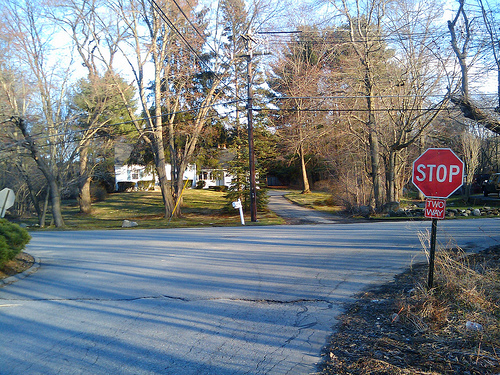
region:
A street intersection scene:
[4, 7, 496, 372]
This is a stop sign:
[411, 145, 466, 294]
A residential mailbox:
[231, 195, 247, 229]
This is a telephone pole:
[234, 19, 272, 223]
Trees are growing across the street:
[1, 0, 498, 225]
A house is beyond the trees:
[108, 134, 263, 194]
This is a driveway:
[260, 186, 350, 228]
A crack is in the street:
[1, 284, 343, 319]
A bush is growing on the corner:
[0, 217, 40, 285]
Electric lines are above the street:
[1, 2, 497, 149]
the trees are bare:
[269, 53, 315, 185]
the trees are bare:
[307, 44, 414, 213]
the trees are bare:
[35, 46, 152, 177]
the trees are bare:
[350, 42, 435, 139]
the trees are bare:
[152, 35, 270, 177]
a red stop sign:
[390, 119, 457, 297]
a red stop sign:
[391, 140, 466, 230]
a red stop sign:
[399, 123, 489, 258]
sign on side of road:
[410, 145, 465, 289]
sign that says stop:
[408, 148, 466, 196]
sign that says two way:
[425, 198, 444, 220]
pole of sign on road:
[427, 218, 438, 288]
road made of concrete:
[8, 225, 347, 373]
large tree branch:
[447, 23, 498, 128]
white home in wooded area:
[108, 137, 249, 192]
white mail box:
[231, 199, 245, 225]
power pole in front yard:
[240, 26, 262, 219]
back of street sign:
[2, 188, 14, 217]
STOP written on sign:
[414, 158, 470, 198]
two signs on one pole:
[417, 140, 449, 215]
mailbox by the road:
[220, 189, 257, 220]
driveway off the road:
[272, 193, 315, 228]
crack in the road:
[177, 275, 244, 312]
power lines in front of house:
[195, 92, 299, 121]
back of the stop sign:
[6, 189, 21, 219]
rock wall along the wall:
[458, 197, 482, 217]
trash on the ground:
[455, 310, 488, 341]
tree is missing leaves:
[42, 14, 96, 51]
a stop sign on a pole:
[374, 97, 499, 311]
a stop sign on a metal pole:
[348, 80, 487, 328]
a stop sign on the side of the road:
[260, 93, 472, 373]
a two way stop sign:
[337, 98, 493, 360]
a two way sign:
[339, 105, 487, 374]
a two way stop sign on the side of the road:
[180, 78, 495, 342]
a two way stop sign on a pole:
[347, 120, 458, 340]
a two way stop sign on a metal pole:
[379, 123, 494, 293]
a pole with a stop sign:
[390, 103, 468, 317]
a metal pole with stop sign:
[391, 141, 483, 316]